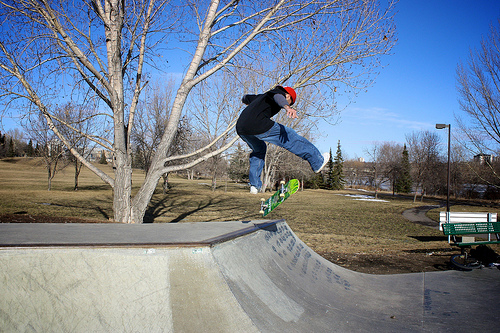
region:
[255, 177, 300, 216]
A gree skateboard.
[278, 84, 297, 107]
Red hat on a guys head.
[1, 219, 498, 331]
A gray skateboard ramp.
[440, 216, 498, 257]
A green metal bench.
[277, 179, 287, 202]
Two wheels on a skateboard to the right.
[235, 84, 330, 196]
A guy in a red hat skateboarding.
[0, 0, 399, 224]
A tree behind a skate ramp.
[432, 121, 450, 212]
A lightpole behind benches.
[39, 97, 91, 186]
Two thin trees in the back left.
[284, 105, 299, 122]
A guy's right side hand.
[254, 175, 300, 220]
bright green skateboard in air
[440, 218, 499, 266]
unused dark green park bench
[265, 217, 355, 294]
graffiti painted on skate slope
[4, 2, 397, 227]
bare tree behind skate slope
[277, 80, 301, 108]
red hat on skateboarder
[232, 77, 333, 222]
teenager performing skateboarding trick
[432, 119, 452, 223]
square black lamp post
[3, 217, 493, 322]
grey concrete skating platform with ramp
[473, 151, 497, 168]
building in distance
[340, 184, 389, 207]
patch of melting snow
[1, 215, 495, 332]
cement skateboard ramp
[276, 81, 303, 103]
red baseball cap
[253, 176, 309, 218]
green skateboard with white wheels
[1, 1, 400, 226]
tall bare leaf tree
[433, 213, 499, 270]
green metal bench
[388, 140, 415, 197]
tall green pine tree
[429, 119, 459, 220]
street lamp on cement sidewalk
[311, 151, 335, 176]
white sneaker in mid air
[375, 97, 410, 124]
white cloud in blue sky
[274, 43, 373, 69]
bare tree branches on tree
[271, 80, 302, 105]
a red hat on the man's head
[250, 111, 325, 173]
the leg of a man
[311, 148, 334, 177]
a white shoe on the man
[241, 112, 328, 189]
a pair of blue jeans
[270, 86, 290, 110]
the arm of a man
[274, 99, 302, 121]
the hand of a man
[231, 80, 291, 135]
a black and gray shirt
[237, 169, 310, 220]
a green skateboard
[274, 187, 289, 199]
a white skateboard wheel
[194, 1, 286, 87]
a branch of the tree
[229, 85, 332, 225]
a skateboarder flying through the air.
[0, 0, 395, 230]
a tall leafless tree.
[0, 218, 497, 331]
a tall cement skateboard ramp.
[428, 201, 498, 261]
a bench in a park.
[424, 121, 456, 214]
a street light in a park.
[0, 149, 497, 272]
a park filled with lots of green grass.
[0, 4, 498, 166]
a blue sky with trees in front of it.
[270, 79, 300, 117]
a man wearing a red hat.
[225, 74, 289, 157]
a man wearing a black jacket.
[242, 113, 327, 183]
a person wearing blue jeans.